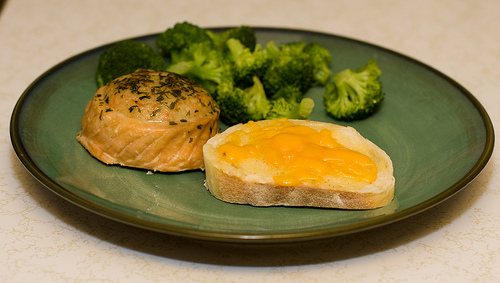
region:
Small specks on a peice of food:
[89, 101, 118, 121]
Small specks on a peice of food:
[120, 83, 149, 119]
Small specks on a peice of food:
[150, 95, 182, 125]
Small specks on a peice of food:
[171, 98, 204, 140]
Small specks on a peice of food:
[183, 100, 218, 118]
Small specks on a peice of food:
[150, 64, 182, 94]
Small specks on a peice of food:
[136, 68, 188, 78]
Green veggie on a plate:
[267, 33, 317, 86]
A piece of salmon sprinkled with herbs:
[86, 72, 215, 172]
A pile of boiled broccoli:
[98, 15, 380, 126]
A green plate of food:
[12, 23, 490, 249]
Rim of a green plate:
[16, 165, 174, 236]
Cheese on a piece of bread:
[217, 120, 382, 189]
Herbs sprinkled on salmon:
[103, 66, 213, 118]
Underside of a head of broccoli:
[320, 65, 382, 117]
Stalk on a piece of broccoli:
[290, 95, 313, 117]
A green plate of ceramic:
[392, 95, 461, 158]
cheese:
[276, 131, 334, 163]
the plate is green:
[385, 117, 437, 151]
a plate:
[407, 109, 446, 149]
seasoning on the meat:
[133, 71, 192, 112]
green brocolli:
[195, 48, 294, 92]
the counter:
[16, 232, 79, 269]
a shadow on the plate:
[95, 174, 152, 201]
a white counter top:
[427, 18, 478, 54]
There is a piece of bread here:
[254, 124, 323, 249]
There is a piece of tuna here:
[117, 68, 162, 208]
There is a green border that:
[239, 228, 244, 249]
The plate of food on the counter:
[16, 3, 496, 275]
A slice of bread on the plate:
[199, 113, 399, 210]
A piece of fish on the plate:
[84, 66, 213, 173]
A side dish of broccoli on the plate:
[95, 25, 391, 128]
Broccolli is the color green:
[130, 31, 350, 107]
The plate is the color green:
[37, 113, 493, 280]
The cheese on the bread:
[236, 118, 373, 190]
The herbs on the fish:
[96, 51, 211, 134]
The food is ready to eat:
[46, 18, 435, 227]